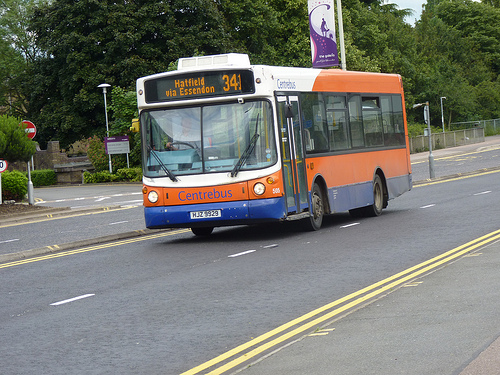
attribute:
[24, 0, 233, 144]
tree — leafy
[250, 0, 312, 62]
tree — leafy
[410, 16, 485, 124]
tree — leafy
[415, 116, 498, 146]
fence — chain link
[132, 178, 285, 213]
lights — on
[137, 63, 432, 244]
bus — orange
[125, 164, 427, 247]
bottom — blue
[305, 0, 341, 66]
flag — white, purple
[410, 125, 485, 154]
fence — silver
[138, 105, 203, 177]
front window — large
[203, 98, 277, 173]
front window — large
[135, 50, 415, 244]
bus — blue, orange, white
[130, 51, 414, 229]
bus — blue, orange, white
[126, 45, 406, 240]
bus — road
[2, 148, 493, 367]
road — large, asphalted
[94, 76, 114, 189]
pole — metal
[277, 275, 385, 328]
lines — yellow, pair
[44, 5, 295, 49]
trees — green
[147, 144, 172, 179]
wiper — windshield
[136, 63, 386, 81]
roof — bus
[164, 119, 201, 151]
driver — bus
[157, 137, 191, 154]
wheel — steering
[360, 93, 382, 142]
window — open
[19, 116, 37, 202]
sign — do not enter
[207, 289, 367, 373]
lines — yellow , ground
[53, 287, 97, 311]
line — white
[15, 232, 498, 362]
road — orange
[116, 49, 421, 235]
bus — orange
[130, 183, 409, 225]
trim — blue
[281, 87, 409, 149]
row — windows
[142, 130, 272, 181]
windshield wipers — a pair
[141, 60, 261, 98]
sign — digital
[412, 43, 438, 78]
leaves — green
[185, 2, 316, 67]
tree — green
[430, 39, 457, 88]
leaves — green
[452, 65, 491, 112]
leaves — green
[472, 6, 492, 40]
leaves — green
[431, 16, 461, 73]
leaves — green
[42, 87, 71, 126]
leaves — green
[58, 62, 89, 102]
leaves — green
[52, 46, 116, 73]
leaves — green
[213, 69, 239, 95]
number — 34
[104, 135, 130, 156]
sign — purple , white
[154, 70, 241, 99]
sign — electronic